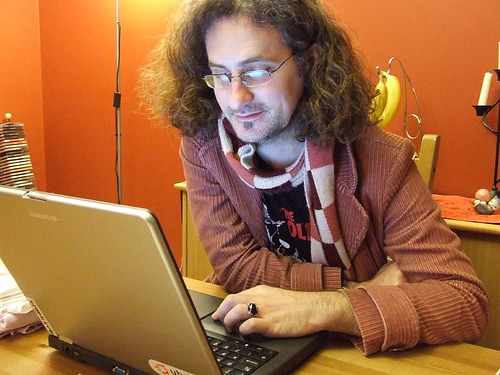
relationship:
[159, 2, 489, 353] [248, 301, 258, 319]
man wearing black ring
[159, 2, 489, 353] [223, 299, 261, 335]
man has finger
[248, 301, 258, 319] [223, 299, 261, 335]
black ring on finger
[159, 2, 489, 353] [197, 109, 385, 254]
man wearing scarf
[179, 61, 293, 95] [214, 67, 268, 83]
eyeglasses over eyes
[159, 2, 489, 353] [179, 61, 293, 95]
man wearing eyeglasses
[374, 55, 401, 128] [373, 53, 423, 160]
bananas hanging on rack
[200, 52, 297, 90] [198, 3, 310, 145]
eyeglasses on face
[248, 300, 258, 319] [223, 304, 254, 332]
black ring on finger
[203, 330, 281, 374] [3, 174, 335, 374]
keyboard on laptop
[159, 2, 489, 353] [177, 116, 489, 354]
man wearing a jacket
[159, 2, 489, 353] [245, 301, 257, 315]
man wearing a ring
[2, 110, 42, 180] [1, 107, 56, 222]
these are cds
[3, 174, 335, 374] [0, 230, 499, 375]
laptop on desk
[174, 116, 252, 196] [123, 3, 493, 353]
pair of eye glasses on man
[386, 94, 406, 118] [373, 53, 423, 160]
banana hanging from rack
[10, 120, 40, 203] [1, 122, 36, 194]
stack of compact discs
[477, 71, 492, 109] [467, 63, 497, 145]
candle in candelabra